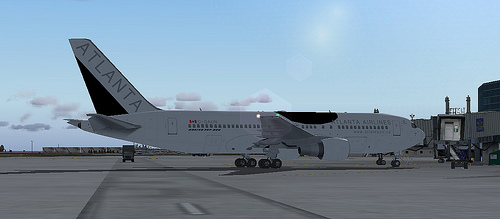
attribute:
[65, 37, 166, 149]
tail — white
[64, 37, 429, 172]
plane — white, large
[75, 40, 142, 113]
lettering — grey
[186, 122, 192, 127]
window — small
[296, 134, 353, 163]
engine — white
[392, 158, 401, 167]
wheel — black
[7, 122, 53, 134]
cloud — grey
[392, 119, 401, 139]
door — white